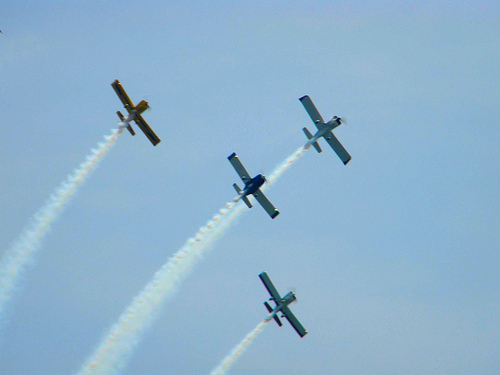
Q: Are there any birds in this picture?
A: No, there are no birds.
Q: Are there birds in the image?
A: No, there are no birds.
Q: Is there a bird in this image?
A: No, there are no birds.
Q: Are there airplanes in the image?
A: Yes, there is an airplane.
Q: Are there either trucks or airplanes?
A: Yes, there is an airplane.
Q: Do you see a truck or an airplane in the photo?
A: Yes, there is an airplane.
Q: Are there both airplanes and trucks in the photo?
A: No, there is an airplane but no trucks.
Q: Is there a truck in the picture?
A: No, there are no trucks.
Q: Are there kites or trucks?
A: No, there are no trucks or kites.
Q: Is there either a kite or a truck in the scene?
A: No, there are no trucks or kites.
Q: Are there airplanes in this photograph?
A: Yes, there is an airplane.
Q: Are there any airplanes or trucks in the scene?
A: Yes, there is an airplane.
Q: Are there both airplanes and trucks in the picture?
A: No, there is an airplane but no trucks.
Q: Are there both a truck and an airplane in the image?
A: No, there is an airplane but no trucks.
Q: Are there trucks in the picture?
A: No, there are no trucks.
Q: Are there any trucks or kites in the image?
A: No, there are no trucks or kites.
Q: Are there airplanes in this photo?
A: Yes, there is an airplane.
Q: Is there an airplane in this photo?
A: Yes, there is an airplane.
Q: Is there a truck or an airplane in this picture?
A: Yes, there is an airplane.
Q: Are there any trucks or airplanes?
A: Yes, there is an airplane.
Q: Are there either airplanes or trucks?
A: Yes, there is an airplane.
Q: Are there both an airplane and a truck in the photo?
A: No, there is an airplane but no trucks.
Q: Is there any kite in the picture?
A: No, there are no kites.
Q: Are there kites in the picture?
A: No, there are no kites.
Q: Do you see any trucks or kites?
A: No, there are no kites or trucks.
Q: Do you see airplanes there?
A: Yes, there is an airplane.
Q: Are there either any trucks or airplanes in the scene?
A: Yes, there is an airplane.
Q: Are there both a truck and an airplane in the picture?
A: No, there is an airplane but no trucks.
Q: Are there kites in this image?
A: No, there are no kites.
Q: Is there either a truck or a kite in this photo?
A: No, there are no kites or trucks.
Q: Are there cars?
A: No, there are no cars.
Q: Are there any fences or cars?
A: No, there are no cars or fences.